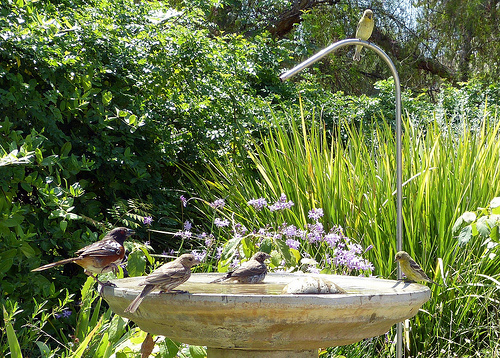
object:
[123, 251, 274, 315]
birds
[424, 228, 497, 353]
plant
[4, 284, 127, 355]
plant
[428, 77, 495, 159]
plant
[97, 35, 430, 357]
bath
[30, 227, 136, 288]
bird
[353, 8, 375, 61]
bird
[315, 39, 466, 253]
pipe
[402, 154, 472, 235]
ground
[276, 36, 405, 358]
faucet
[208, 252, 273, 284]
bird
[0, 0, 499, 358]
garden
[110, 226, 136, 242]
head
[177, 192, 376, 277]
flower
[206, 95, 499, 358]
bushes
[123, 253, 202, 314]
bird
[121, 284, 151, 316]
tail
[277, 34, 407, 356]
pipe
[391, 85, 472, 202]
leaves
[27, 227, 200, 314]
birds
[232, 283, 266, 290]
water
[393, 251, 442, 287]
bird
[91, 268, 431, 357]
pool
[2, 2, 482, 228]
trees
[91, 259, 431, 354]
bird bath